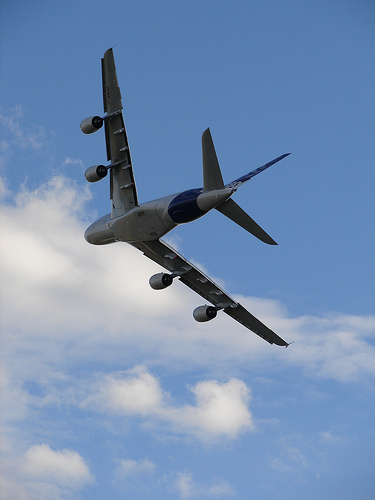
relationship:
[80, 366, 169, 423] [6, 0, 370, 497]
cloud in sky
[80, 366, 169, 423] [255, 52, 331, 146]
cloud in sky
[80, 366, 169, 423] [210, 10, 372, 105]
cloud in sky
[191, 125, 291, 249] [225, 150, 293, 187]
tail has wing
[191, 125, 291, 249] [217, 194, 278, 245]
tail has wing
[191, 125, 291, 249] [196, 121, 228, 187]
tail has wing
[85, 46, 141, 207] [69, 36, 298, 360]
left wing on airplane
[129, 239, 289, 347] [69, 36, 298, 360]
wing on airplane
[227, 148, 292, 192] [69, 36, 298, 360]
blue tail on airplane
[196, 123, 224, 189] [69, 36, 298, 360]
wing on airplane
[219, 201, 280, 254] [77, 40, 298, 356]
right wing on plane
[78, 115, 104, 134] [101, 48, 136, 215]
turbine engine on wing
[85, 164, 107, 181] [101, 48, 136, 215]
turbine engine on wing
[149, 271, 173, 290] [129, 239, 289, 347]
turbine engine on wing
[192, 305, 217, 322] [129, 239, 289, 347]
turbine engine on wing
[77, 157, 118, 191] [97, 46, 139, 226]
propeller on wing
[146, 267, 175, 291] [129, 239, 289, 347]
propeller on wing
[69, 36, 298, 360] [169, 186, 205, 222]
airplane has stripe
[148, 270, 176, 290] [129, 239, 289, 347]
engine on wing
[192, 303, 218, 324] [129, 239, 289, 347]
engine on wing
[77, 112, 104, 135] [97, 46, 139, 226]
engine on wing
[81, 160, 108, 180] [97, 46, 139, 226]
engine on wing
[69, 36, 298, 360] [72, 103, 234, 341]
airplane has propellers